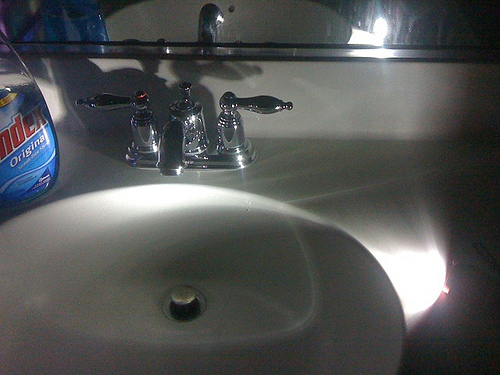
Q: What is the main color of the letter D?
A: Red.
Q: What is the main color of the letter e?
A: Red.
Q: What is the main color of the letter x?
A: Red.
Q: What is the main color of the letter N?
A: Red.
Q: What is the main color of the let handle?
A: Silver.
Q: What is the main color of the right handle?
A: Gray.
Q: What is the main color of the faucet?
A: Gray.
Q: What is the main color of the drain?
A: Gray.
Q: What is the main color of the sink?
A: White.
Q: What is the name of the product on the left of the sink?
A: Windex.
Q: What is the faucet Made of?
A: Metal.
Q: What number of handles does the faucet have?
A: 2.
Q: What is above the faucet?
A: Mirror.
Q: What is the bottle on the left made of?
A: Plastic.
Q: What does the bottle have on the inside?
A: Window cleaner.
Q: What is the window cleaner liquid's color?
A: Blue.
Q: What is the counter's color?
A: White.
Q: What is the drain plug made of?
A: Metal.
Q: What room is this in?
A: The bathroom.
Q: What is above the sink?
A: The mirror.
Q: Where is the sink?
A: Below the mirror.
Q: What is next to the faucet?
A: Windex.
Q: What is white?
A: The sink.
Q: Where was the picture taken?
A: In a bathroom.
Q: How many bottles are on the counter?
A: One.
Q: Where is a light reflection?
A: In mirror and on counter.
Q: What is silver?
A: Faucet handles.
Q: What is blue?
A: Windex liquid.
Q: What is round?
A: Sink.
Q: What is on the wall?
A: A mirror.